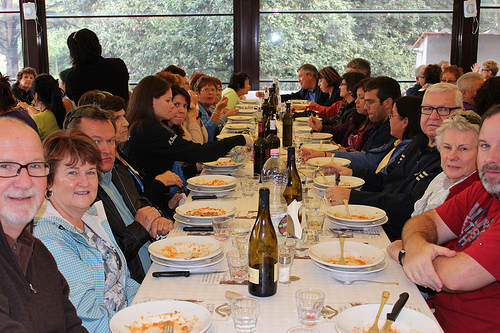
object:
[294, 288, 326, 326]
cup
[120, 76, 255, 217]
woman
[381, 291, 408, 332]
knife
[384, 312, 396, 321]
part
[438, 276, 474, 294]
elbow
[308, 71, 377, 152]
person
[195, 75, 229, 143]
person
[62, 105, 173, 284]
person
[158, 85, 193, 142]
person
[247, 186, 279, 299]
bottle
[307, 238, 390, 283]
plate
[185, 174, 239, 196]
plate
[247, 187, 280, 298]
wine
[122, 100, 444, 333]
table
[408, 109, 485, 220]
person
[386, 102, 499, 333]
man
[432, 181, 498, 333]
shirt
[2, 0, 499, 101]
windows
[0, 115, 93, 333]
man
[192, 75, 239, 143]
person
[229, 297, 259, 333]
glass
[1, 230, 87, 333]
sweater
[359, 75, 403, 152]
person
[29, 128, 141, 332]
person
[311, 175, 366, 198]
plate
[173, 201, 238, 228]
plate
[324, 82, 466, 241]
person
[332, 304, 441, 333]
plate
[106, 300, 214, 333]
plate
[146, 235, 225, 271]
plate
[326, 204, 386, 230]
plate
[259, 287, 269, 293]
part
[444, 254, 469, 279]
part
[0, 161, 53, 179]
glasses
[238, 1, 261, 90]
trim